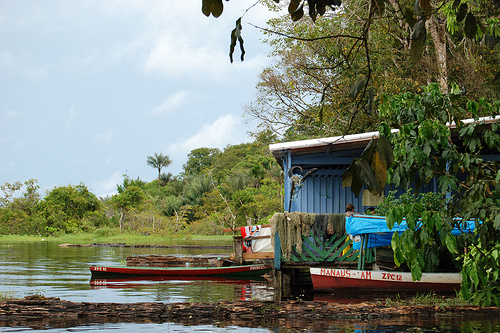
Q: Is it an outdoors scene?
A: Yes, it is outdoors.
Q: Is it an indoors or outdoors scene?
A: It is outdoors.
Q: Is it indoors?
A: No, it is outdoors.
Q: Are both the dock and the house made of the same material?
A: Yes, both the dock and the house are made of wood.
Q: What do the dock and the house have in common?
A: The material, both the dock and the house are wooden.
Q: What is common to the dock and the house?
A: The material, both the dock and the house are wooden.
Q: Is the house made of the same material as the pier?
A: Yes, both the house and the pier are made of wood.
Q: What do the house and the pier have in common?
A: The material, both the house and the pier are wooden.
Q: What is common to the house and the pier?
A: The material, both the house and the pier are wooden.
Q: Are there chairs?
A: No, there are no chairs.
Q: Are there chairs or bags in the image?
A: No, there are no chairs or bags.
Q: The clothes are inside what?
A: The clothes are inside the house.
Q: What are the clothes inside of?
A: The clothes are inside the house.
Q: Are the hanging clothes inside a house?
A: Yes, the clothes are inside a house.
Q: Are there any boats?
A: Yes, there is a boat.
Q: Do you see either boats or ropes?
A: Yes, there is a boat.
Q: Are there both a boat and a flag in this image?
A: No, there is a boat but no flags.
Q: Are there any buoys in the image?
A: No, there are no buoys.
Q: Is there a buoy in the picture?
A: No, there are no buoys.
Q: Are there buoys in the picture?
A: No, there are no buoys.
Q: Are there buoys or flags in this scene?
A: No, there are no buoys or flags.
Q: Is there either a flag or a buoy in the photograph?
A: No, there are no buoys or flags.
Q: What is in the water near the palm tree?
A: The boat is in the water.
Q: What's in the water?
A: The boat is in the water.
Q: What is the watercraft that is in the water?
A: The watercraft is a boat.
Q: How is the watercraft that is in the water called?
A: The watercraft is a boat.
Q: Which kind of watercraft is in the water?
A: The watercraft is a boat.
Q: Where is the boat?
A: The boat is in the water.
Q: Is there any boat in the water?
A: Yes, there is a boat in the water.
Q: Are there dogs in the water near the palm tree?
A: No, there is a boat in the water.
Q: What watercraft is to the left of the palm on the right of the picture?
A: The watercraft is a boat.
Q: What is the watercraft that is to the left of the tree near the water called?
A: The watercraft is a boat.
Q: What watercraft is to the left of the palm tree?
A: The watercraft is a boat.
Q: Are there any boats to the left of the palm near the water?
A: Yes, there is a boat to the left of the palm tree.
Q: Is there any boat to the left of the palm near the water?
A: Yes, there is a boat to the left of the palm tree.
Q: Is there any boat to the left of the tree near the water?
A: Yes, there is a boat to the left of the palm tree.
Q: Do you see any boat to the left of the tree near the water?
A: Yes, there is a boat to the left of the palm tree.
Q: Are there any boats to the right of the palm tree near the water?
A: No, the boat is to the left of the palm.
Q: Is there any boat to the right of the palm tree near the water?
A: No, the boat is to the left of the palm.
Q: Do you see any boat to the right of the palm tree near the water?
A: No, the boat is to the left of the palm.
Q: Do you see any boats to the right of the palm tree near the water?
A: No, the boat is to the left of the palm.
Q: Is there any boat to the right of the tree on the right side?
A: No, the boat is to the left of the palm.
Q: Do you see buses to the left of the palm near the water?
A: No, there is a boat to the left of the palm.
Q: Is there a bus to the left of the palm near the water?
A: No, there is a boat to the left of the palm.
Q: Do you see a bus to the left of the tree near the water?
A: No, there is a boat to the left of the palm.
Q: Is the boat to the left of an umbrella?
A: No, the boat is to the left of the palm.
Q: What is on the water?
A: The boat is on the water.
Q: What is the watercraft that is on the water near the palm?
A: The watercraft is a boat.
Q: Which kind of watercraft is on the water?
A: The watercraft is a boat.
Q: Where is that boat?
A: The boat is on the water.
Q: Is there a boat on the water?
A: Yes, there is a boat on the water.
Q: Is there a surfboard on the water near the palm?
A: No, there is a boat on the water.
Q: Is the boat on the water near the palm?
A: Yes, the boat is on the water.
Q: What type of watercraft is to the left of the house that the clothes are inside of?
A: The watercraft is a boat.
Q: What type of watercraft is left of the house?
A: The watercraft is a boat.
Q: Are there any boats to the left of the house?
A: Yes, there is a boat to the left of the house.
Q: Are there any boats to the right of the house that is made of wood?
A: No, the boat is to the left of the house.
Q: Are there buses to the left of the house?
A: No, there is a boat to the left of the house.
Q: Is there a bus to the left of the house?
A: No, there is a boat to the left of the house.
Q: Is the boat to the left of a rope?
A: No, the boat is to the left of the house.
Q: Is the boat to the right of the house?
A: No, the boat is to the left of the house.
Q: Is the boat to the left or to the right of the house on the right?
A: The boat is to the left of the house.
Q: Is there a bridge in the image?
A: No, there are no bridges.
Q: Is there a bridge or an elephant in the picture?
A: No, there are no bridges or elephants.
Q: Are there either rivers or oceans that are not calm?
A: No, there is a river but it is calm.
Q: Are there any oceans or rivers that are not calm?
A: No, there is a river but it is calm.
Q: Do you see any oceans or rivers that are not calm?
A: No, there is a river but it is calm.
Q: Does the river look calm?
A: Yes, the river is calm.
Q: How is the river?
A: The river is calm.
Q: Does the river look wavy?
A: No, the river is calm.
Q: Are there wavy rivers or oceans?
A: No, there is a river but it is calm.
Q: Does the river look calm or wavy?
A: The river is calm.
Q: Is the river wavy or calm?
A: The river is calm.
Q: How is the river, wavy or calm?
A: The river is calm.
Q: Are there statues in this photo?
A: No, there are no statues.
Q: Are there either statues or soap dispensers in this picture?
A: No, there are no statues or soap dispensers.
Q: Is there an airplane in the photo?
A: No, there are no airplanes.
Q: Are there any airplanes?
A: No, there are no airplanes.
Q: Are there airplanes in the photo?
A: No, there are no airplanes.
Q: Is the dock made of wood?
A: Yes, the dock is made of wood.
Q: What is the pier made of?
A: The pier is made of wood.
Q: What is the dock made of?
A: The pier is made of wood.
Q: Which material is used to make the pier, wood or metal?
A: The pier is made of wood.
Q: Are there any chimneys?
A: No, there are no chimneys.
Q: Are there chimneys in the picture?
A: No, there are no chimneys.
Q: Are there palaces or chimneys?
A: No, there are no chimneys or palaces.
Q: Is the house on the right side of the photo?
A: Yes, the house is on the right of the image.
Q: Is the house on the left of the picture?
A: No, the house is on the right of the image.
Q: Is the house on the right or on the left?
A: The house is on the right of the image.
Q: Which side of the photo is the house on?
A: The house is on the right of the image.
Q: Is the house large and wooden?
A: Yes, the house is large and wooden.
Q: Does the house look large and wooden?
A: Yes, the house is large and wooden.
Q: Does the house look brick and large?
A: No, the house is large but wooden.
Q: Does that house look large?
A: Yes, the house is large.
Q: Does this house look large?
A: Yes, the house is large.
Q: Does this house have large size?
A: Yes, the house is large.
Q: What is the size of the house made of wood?
A: The house is large.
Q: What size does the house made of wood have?
A: The house has large size.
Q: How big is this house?
A: The house is large.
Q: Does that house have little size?
A: No, the house is large.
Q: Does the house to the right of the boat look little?
A: No, the house is large.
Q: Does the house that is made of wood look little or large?
A: The house is large.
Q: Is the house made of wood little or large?
A: The house is large.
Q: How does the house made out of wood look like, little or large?
A: The house is large.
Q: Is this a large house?
A: Yes, this is a large house.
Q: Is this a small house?
A: No, this is a large house.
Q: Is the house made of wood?
A: Yes, the house is made of wood.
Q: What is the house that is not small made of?
A: The house is made of wood.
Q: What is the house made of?
A: The house is made of wood.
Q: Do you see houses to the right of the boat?
A: Yes, there is a house to the right of the boat.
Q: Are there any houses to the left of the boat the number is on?
A: No, the house is to the right of the boat.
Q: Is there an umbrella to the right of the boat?
A: No, there is a house to the right of the boat.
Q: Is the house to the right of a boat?
A: Yes, the house is to the right of a boat.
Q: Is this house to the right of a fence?
A: No, the house is to the right of a boat.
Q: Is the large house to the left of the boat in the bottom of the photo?
A: No, the house is to the right of the boat.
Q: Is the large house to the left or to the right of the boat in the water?
A: The house is to the right of the boat.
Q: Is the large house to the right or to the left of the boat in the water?
A: The house is to the right of the boat.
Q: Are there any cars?
A: No, there are no cars.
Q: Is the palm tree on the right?
A: Yes, the palm tree is on the right of the image.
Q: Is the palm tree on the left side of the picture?
A: No, the palm tree is on the right of the image.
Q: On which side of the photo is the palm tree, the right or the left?
A: The palm tree is on the right of the image.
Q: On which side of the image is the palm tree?
A: The palm tree is on the right of the image.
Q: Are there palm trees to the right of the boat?
A: Yes, there is a palm tree to the right of the boat.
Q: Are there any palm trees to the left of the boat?
A: No, the palm tree is to the right of the boat.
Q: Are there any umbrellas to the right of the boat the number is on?
A: No, there is a palm tree to the right of the boat.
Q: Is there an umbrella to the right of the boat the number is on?
A: No, there is a palm tree to the right of the boat.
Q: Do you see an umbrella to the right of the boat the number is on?
A: No, there is a palm tree to the right of the boat.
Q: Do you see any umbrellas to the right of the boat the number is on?
A: No, there is a palm tree to the right of the boat.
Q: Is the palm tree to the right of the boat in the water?
A: Yes, the palm tree is to the right of the boat.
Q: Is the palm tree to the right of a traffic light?
A: No, the palm tree is to the right of the boat.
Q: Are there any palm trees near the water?
A: Yes, there is a palm tree near the water.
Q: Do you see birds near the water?
A: No, there is a palm tree near the water.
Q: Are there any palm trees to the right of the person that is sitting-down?
A: Yes, there is a palm tree to the right of the person.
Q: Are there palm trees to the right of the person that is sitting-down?
A: Yes, there is a palm tree to the right of the person.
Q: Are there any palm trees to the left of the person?
A: No, the palm tree is to the right of the person.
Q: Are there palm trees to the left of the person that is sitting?
A: No, the palm tree is to the right of the person.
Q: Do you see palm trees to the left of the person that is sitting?
A: No, the palm tree is to the right of the person.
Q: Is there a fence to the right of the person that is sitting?
A: No, there is a palm tree to the right of the person.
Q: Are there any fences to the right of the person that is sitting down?
A: No, there is a palm tree to the right of the person.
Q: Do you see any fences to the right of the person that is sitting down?
A: No, there is a palm tree to the right of the person.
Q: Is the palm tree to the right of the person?
A: Yes, the palm tree is to the right of the person.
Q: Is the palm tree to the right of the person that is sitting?
A: Yes, the palm tree is to the right of the person.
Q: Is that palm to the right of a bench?
A: No, the palm is to the right of the person.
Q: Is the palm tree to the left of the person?
A: No, the palm tree is to the right of the person.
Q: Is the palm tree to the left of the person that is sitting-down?
A: No, the palm tree is to the right of the person.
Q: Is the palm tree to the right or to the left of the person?
A: The palm tree is to the right of the person.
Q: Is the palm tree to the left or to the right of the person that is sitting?
A: The palm tree is to the right of the person.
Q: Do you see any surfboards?
A: No, there are no surfboards.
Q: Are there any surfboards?
A: No, there are no surfboards.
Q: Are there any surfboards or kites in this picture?
A: No, there are no surfboards or kites.